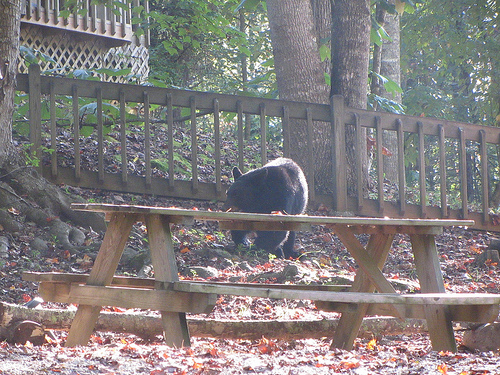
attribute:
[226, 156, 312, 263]
bear — brown, black, walking, dark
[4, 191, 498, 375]
leaves — red, coloful, colorful, brown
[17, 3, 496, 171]
leaves — green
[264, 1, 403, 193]
tree trunk — brown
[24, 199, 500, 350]
bench — brown, wooden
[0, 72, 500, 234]
fence — wooden, tall, long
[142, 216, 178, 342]
post — wooden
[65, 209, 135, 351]
post — wooden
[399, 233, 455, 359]
post — wooden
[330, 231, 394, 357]
post — wooden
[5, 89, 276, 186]
plants — green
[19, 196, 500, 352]
picnic table — wooden, empty, brown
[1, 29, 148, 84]
lattice — wooden